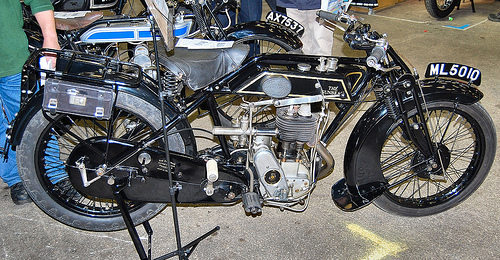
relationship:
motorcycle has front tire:
[21, 3, 496, 256] [345, 67, 496, 223]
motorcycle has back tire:
[21, 3, 496, 256] [4, 61, 193, 235]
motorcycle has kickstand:
[21, 3, 496, 256] [94, 146, 216, 257]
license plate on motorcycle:
[429, 59, 480, 95] [21, 3, 496, 256]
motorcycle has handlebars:
[21, 3, 496, 256] [348, 29, 405, 88]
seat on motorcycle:
[138, 43, 253, 100] [21, 3, 496, 256]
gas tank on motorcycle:
[252, 64, 292, 103] [21, 3, 496, 256]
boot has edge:
[49, 178, 80, 201] [58, 195, 78, 205]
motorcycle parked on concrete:
[21, 13, 496, 257] [8, 13, 495, 258]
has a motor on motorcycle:
[243, 136, 328, 207] [21, 13, 496, 257]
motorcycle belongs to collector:
[21, 3, 496, 256] [0, 0, 101, 230]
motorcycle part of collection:
[21, 13, 496, 257] [15, 11, 497, 235]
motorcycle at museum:
[21, 13, 496, 257] [5, 6, 493, 252]